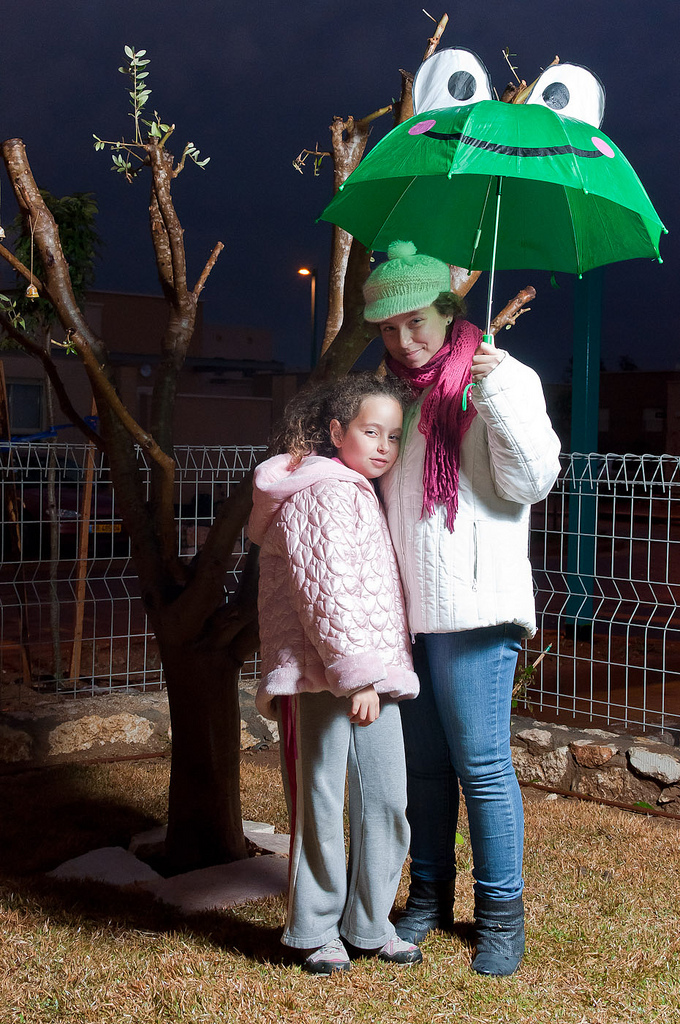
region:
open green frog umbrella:
[318, 47, 669, 350]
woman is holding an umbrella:
[363, 238, 561, 978]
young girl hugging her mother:
[248, 368, 428, 972]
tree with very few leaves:
[5, 9, 535, 883]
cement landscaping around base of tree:
[44, 811, 292, 913]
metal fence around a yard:
[0, 438, 676, 739]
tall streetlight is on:
[293, 261, 320, 363]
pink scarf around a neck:
[386, 318, 488, 535]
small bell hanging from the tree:
[21, 213, 44, 302]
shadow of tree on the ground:
[0, 751, 312, 970]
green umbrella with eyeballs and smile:
[305, 46, 645, 279]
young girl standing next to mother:
[254, 364, 440, 969]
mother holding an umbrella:
[349, 235, 542, 973]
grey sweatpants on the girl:
[270, 683, 445, 981]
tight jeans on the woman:
[408, 625, 542, 972]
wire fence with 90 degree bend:
[1, 434, 678, 742]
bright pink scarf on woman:
[384, 319, 486, 527]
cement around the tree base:
[38, 805, 345, 921]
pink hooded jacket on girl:
[239, 446, 427, 703]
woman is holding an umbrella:
[313, 43, 667, 408]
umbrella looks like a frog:
[314, 42, 670, 392]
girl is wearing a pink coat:
[218, 374, 428, 974]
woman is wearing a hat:
[351, 235, 448, 316]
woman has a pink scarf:
[374, 315, 477, 517]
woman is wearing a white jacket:
[380, 350, 544, 638]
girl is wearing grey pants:
[268, 689, 395, 949]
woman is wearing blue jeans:
[393, 602, 527, 903]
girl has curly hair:
[262, 367, 407, 467]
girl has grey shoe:
[288, 929, 352, 976]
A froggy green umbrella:
[309, 43, 672, 413]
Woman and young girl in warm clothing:
[236, 236, 571, 979]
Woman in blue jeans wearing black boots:
[355, 238, 564, 978]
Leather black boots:
[391, 870, 527, 980]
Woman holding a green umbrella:
[302, 43, 669, 979]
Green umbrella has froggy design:
[310, 44, 673, 415]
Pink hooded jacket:
[244, 446, 422, 721]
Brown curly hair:
[258, 372, 407, 472]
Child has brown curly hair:
[245, 370, 422, 974]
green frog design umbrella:
[318, 45, 672, 282]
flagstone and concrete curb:
[0, 675, 671, 822]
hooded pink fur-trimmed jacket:
[240, 446, 422, 721]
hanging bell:
[29, 205, 41, 303]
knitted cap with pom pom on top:
[360, 235, 447, 326]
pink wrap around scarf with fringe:
[396, 314, 472, 534]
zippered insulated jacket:
[373, 345, 563, 647]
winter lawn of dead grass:
[1, 739, 678, 1022]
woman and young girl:
[239, 233, 563, 977]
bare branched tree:
[0, 6, 542, 866]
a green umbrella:
[313, 30, 670, 286]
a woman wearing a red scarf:
[351, 232, 566, 992]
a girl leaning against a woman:
[232, 368, 457, 977]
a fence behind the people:
[0, 432, 675, 752]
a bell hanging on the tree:
[19, 205, 51, 312]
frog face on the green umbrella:
[396, 35, 625, 174]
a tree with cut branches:
[3, 12, 555, 886]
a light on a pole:
[287, 254, 328, 363]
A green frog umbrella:
[309, 45, 667, 412]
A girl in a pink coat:
[244, 370, 424, 973]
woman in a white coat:
[359, 238, 560, 976]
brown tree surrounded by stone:
[0, 9, 558, 918]